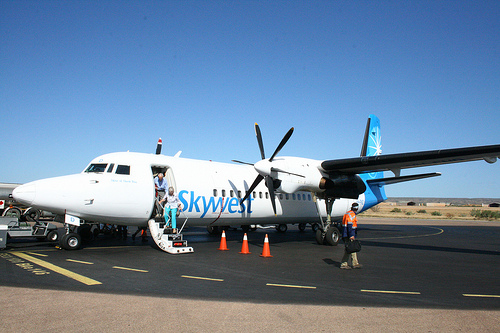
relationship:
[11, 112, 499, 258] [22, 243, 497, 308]
airplane on runway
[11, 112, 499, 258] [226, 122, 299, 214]
airplane has propeller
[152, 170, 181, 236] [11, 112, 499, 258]
passengers leaving airplane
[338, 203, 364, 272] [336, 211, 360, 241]
man with orange jacket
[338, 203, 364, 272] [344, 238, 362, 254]
man walking black bag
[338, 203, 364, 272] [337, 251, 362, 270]
man has brown pants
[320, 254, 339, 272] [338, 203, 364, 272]
shadow of man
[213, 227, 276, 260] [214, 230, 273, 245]
cones with white tips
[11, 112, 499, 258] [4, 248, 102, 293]
airplane behind yellow stripe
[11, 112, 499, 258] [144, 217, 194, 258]
airplane has ladder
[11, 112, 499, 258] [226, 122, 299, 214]
airplane has roters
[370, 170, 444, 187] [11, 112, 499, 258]
back wing on airplane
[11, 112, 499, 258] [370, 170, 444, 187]
airplane has back wing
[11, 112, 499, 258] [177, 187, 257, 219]
airplane belongs to skywest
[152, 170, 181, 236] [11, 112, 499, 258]
passengers deboarding airplane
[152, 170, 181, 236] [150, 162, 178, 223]
passengers seen in doorway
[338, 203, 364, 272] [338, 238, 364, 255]
man carrying black bag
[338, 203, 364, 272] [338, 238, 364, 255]
man with black bag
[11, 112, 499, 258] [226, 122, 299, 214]
airplane has black propeller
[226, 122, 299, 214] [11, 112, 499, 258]
black propeller on airplane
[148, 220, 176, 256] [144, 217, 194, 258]
side of staircase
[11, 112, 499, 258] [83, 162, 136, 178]
airplane has front windows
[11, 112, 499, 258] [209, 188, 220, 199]
airplane has window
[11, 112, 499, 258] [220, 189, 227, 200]
airplane has window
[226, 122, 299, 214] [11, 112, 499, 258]
propeller on airplane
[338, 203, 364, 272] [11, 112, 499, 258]
man with bag looking at airplane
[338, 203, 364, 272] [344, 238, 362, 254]
man with bag has black bag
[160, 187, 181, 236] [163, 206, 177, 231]
woman has green pants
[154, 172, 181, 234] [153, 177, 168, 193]
passengers with blue shirt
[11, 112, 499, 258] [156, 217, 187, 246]
airplane has steps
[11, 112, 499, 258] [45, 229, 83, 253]
airplane has front black tires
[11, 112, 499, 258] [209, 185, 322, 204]
airplane with passenger windows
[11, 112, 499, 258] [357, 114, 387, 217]
airplane has blue tail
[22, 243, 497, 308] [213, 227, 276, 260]
runway has three cones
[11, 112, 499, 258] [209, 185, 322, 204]
airplane has windows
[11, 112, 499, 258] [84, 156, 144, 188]
airplane has cockpit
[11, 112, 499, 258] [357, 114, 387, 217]
airplane has tail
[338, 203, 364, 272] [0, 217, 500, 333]
man walking runway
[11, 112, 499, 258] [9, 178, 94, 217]
airplane has sharp nose